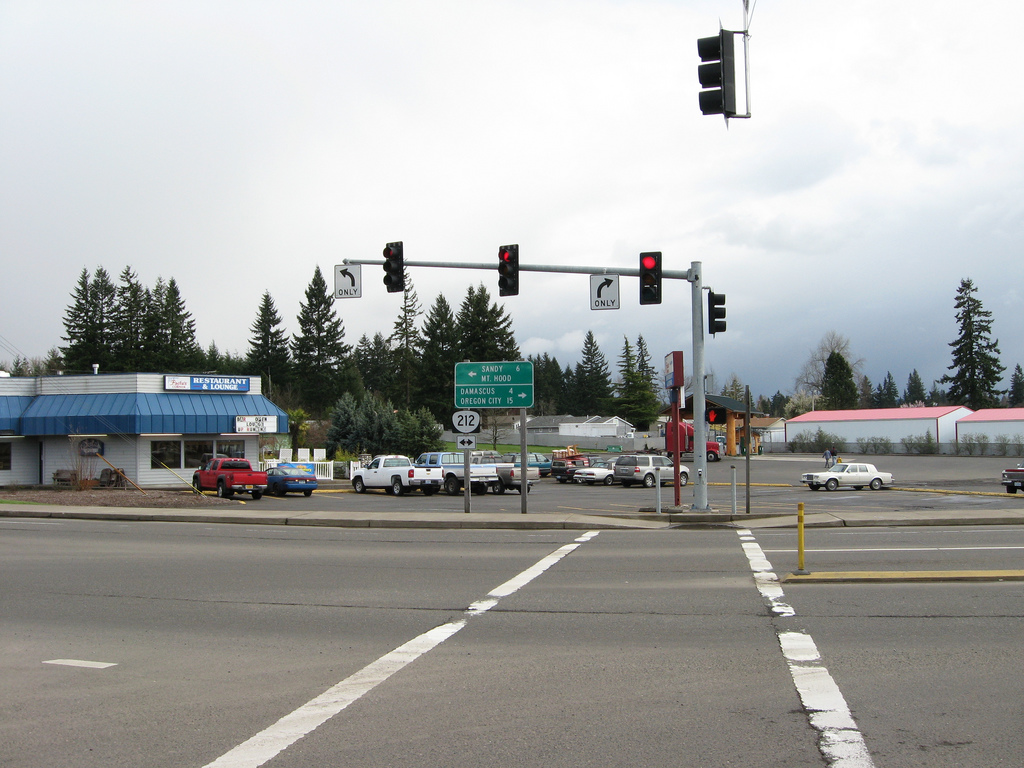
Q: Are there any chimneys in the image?
A: No, there are no chimneys.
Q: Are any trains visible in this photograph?
A: No, there are no trains.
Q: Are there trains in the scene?
A: No, there are no trains.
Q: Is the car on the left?
A: No, the car is on the right of the image.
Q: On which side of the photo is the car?
A: The car is on the right of the image.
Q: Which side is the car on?
A: The car is on the right of the image.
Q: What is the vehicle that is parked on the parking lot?
A: The vehicle is a car.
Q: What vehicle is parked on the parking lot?
A: The vehicle is a car.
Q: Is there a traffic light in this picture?
A: Yes, there is a traffic light.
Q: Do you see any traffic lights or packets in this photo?
A: Yes, there is a traffic light.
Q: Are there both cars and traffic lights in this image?
A: Yes, there are both a traffic light and cars.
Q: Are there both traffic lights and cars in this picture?
A: Yes, there are both a traffic light and cars.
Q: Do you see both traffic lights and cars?
A: Yes, there are both a traffic light and cars.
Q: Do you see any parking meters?
A: No, there are no parking meters.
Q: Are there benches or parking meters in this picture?
A: No, there are no parking meters or benches.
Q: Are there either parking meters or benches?
A: No, there are no parking meters or benches.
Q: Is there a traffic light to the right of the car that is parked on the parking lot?
A: No, the traffic light is to the left of the car.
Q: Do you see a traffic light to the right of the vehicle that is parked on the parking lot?
A: No, the traffic light is to the left of the car.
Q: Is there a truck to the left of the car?
A: No, there is a traffic light to the left of the car.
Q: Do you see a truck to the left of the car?
A: No, there is a traffic light to the left of the car.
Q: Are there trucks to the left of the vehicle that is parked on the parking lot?
A: No, there is a traffic light to the left of the car.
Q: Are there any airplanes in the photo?
A: No, there are no airplanes.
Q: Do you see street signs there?
A: Yes, there is a street sign.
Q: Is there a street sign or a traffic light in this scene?
A: Yes, there is a street sign.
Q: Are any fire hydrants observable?
A: No, there are no fire hydrants.